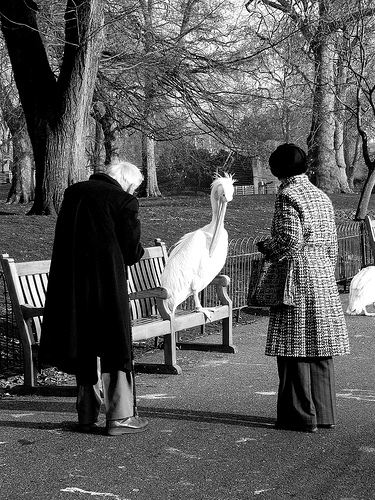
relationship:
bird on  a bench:
[149, 172, 243, 302] [0, 236, 239, 398]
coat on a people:
[283, 265, 319, 316] [254, 142, 350, 433]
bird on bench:
[203, 193, 233, 201] [19, 287, 225, 306]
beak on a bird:
[205, 196, 227, 257] [159, 169, 239, 321]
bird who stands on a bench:
[159, 169, 239, 321] [19, 242, 239, 357]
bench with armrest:
[10, 236, 241, 401] [209, 273, 238, 305]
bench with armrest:
[10, 236, 241, 401] [133, 286, 171, 322]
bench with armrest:
[10, 236, 241, 401] [24, 301, 44, 322]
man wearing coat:
[36, 154, 149, 435] [34, 171, 146, 387]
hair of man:
[109, 160, 148, 192] [37, 154, 149, 435]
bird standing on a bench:
[159, 169, 239, 321] [0, 236, 239, 398]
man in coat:
[37, 154, 149, 435] [38, 172, 146, 374]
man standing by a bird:
[37, 154, 149, 435] [159, 169, 239, 321]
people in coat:
[250, 141, 352, 437] [264, 175, 351, 357]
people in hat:
[254, 142, 350, 433] [267, 142, 307, 180]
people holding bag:
[254, 142, 350, 433] [246, 239, 300, 310]